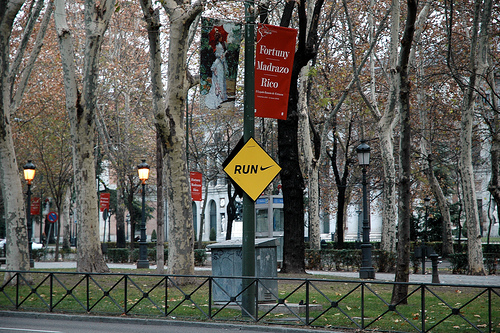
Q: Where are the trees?
A: In the park.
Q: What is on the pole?
A: A yellow sign.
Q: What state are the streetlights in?
A: On.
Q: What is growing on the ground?
A: Grass.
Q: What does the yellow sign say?
A: Run.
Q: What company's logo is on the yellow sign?
A: Nike.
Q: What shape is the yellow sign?
A: Diamond.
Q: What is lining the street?
A: A metal fence.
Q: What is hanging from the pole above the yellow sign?
A: Banners.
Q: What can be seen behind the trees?
A: A building.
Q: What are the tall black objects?
A: Street lights.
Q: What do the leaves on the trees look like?
A: Brown and dead.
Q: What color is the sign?
A: Yellow.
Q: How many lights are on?
A: Two.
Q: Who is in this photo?
A: Nobody.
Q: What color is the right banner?
A: Red.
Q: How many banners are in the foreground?
A: Two.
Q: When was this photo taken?
A: Daytime.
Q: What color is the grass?
A: Green.